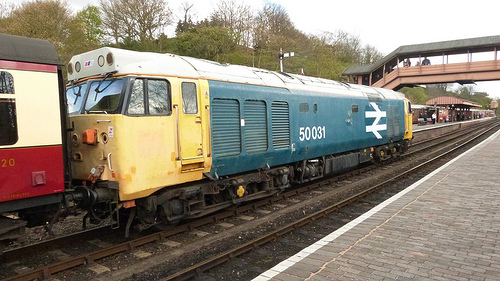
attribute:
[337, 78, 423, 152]
engine — blue